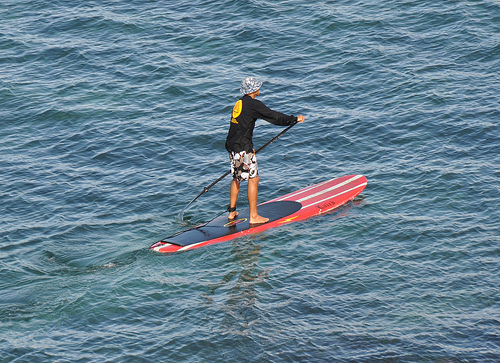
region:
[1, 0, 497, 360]
Waves in the water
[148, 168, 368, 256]
Red standing paddle board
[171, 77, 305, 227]
Man holding a paddle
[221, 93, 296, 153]
Black long sleeve shirt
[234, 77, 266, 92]
Gray and white camo hat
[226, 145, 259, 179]
Brown blue and white shorts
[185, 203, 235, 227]
Black ankle board strap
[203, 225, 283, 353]
Man's reflection in water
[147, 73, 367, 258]
Man paddle boarding in water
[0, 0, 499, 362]
Blue water with waves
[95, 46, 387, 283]
a man in the middle of the water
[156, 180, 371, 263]
red and white wake board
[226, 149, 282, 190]
floral swim trunks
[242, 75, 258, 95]
gilligan hat on his head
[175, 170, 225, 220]
paddle for rowing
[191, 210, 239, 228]
leash to keep him connected to board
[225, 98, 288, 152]
black and yellow long sleeved shirt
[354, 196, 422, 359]
portion of ocean water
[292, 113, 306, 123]
mans right hand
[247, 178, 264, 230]
right leg of man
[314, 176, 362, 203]
red and white paddle board in ocean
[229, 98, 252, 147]
yellow and black shirt worn by man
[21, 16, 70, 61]
blue and white water in ocean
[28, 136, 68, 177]
blue and white water in ocean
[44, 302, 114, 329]
blue and white water in ocean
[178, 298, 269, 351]
blue and white water in ocean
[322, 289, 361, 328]
blue and white water in ocean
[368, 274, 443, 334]
blue and white water in ocean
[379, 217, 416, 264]
blue and white water in ocean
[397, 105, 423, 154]
blue and white water in ocean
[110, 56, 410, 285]
guy on the beach water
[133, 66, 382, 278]
guy paddle boarding on the beach water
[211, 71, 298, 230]
guy wearing hat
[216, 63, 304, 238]
guy wearing fisherman hat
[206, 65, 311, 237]
guy wearing black and yellow long sleeve shirt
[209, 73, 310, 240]
guy wearing shorts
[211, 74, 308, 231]
guy wearing swim shirts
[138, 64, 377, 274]
guy standing on long board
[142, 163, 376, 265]
red and white board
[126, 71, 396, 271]
guy paddling through water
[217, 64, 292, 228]
man wearing a black tshirt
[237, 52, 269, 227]
man wearing a hat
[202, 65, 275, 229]
man wearing shorts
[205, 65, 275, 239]
man standing on a surf board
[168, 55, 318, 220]
man holding an oar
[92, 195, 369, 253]
red and white surf board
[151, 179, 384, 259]
surf board in water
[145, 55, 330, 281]
man floating on surf board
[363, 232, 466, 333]
blue water with a man floating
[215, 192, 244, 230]
man ankle with black cuff